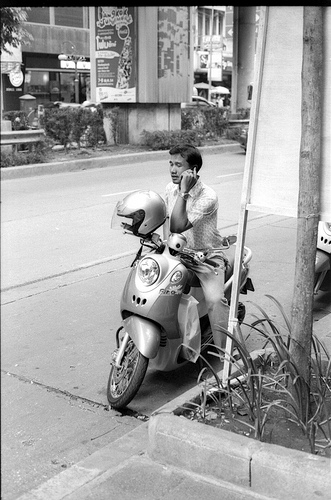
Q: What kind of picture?
A: Black and white.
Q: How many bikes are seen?
A: 2.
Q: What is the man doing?
A: Speaking in phone.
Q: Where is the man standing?
A: In the road side.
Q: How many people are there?
A: One.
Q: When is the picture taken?
A: Daytime.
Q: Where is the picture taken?
A: On a sidewalk.